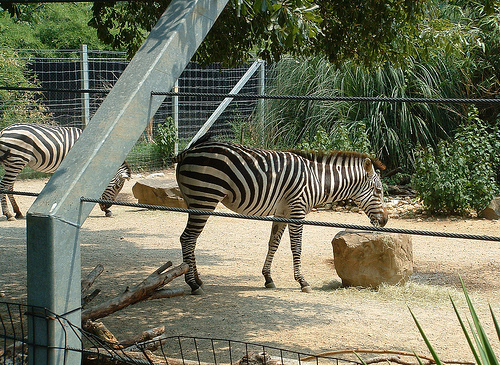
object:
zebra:
[179, 142, 389, 295]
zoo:
[0, 0, 500, 309]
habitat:
[9, 44, 287, 170]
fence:
[174, 76, 272, 139]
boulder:
[61, 0, 234, 166]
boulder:
[332, 230, 411, 290]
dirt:
[258, 290, 423, 364]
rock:
[331, 228, 412, 287]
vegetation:
[384, 113, 498, 182]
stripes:
[223, 157, 307, 195]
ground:
[93, 293, 382, 349]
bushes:
[367, 61, 481, 146]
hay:
[413, 269, 499, 312]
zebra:
[0, 122, 132, 221]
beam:
[26, 151, 131, 364]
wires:
[177, 78, 257, 107]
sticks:
[215, 93, 277, 141]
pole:
[80, 43, 89, 123]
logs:
[80, 262, 188, 324]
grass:
[307, 126, 369, 154]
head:
[350, 152, 388, 228]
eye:
[376, 189, 381, 194]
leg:
[288, 204, 315, 294]